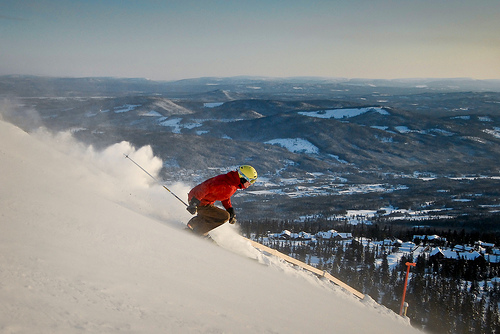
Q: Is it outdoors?
A: Yes, it is outdoors.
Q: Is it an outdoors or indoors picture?
A: It is outdoors.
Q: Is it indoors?
A: No, it is outdoors.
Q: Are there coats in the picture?
A: Yes, there is a coat.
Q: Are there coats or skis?
A: Yes, there is a coat.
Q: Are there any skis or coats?
A: Yes, there is a coat.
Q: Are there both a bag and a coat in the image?
A: No, there is a coat but no bags.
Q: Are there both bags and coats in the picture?
A: No, there is a coat but no bags.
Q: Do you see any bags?
A: No, there are no bags.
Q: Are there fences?
A: No, there are no fences.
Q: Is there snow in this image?
A: Yes, there is snow.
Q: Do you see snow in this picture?
A: Yes, there is snow.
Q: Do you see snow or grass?
A: Yes, there is snow.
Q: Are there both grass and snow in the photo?
A: No, there is snow but no grass.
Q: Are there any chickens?
A: No, there are no chickens.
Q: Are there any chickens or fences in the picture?
A: No, there are no chickens or fences.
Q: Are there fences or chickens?
A: No, there are no chickens or fences.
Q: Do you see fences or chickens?
A: No, there are no chickens or fences.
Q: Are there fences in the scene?
A: No, there are no fences.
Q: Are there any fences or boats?
A: No, there are no fences or boats.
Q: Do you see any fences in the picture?
A: No, there are no fences.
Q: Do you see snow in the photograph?
A: Yes, there is snow.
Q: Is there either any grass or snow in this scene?
A: Yes, there is snow.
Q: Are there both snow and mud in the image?
A: No, there is snow but no mud.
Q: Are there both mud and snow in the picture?
A: No, there is snow but no mud.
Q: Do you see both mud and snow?
A: No, there is snow but no mud.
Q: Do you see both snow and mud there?
A: No, there is snow but no mud.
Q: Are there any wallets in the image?
A: No, there are no wallets.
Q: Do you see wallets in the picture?
A: No, there are no wallets.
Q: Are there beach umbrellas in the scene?
A: No, there are no beach umbrellas.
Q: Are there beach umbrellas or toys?
A: No, there are no beach umbrellas or toys.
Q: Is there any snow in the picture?
A: Yes, there is snow.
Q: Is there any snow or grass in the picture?
A: Yes, there is snow.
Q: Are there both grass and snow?
A: No, there is snow but no grass.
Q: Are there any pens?
A: No, there are no pens.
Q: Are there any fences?
A: No, there are no fences.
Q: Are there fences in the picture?
A: No, there are no fences.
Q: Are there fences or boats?
A: No, there are no fences or boats.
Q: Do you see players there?
A: No, there are no players.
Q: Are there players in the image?
A: No, there are no players.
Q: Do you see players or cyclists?
A: No, there are no players or cyclists.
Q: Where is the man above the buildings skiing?
A: The man is skiing in the snow.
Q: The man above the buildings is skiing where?
A: The man is skiing in the snow.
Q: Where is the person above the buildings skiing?
A: The man is skiing in the snow.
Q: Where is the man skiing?
A: The man is skiing in the snow.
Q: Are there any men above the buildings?
A: Yes, there is a man above the buildings.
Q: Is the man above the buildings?
A: Yes, the man is above the buildings.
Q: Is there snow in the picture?
A: Yes, there is snow.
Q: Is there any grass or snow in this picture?
A: Yes, there is snow.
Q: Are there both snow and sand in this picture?
A: No, there is snow but no sand.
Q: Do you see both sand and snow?
A: No, there is snow but no sand.